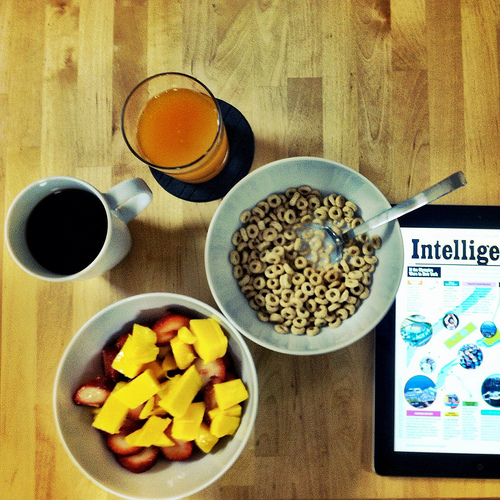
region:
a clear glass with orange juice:
[116, 65, 235, 190]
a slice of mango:
[184, 315, 234, 367]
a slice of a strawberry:
[68, 375, 115, 412]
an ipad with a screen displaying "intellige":
[368, 182, 498, 480]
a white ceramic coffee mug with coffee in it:
[3, 162, 154, 288]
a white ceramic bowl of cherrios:
[202, 150, 410, 355]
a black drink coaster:
[139, 89, 267, 204]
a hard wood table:
[1, 0, 498, 496]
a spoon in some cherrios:
[294, 165, 474, 275]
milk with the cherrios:
[283, 215, 363, 273]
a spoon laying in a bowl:
[221, 171, 461, 255]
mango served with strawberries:
[101, 325, 201, 445]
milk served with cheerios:
[280, 235, 346, 299]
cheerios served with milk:
[283, 232, 358, 339]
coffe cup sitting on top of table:
[1, 185, 157, 295]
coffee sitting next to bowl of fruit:
[16, 176, 153, 317]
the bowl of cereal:
[203, 155, 403, 355]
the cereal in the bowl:
[228, 185, 381, 336]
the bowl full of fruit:
[52, 291, 257, 498]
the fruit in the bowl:
[72, 313, 248, 473]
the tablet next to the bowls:
[371, 204, 498, 479]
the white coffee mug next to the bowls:
[4, 176, 152, 282]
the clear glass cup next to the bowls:
[120, 71, 228, 183]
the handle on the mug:
[104, 177, 151, 224]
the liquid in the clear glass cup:
[137, 88, 229, 184]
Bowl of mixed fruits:
[47, 292, 249, 498]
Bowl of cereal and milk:
[206, 157, 401, 359]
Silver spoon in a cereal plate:
[291, 169, 480, 270]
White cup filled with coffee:
[8, 165, 150, 280]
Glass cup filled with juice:
[118, 71, 231, 184]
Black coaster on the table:
[149, 95, 258, 199]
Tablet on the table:
[368, 200, 498, 478]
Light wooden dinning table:
[0, 0, 499, 70]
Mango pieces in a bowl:
[107, 340, 199, 420]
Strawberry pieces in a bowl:
[107, 430, 175, 470]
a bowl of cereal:
[212, 178, 412, 343]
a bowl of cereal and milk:
[217, 149, 401, 340]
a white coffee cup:
[4, 163, 119, 297]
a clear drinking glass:
[118, 43, 239, 188]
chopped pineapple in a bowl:
[94, 321, 220, 438]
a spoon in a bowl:
[280, 159, 464, 276]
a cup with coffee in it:
[5, 156, 109, 301]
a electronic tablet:
[362, 178, 489, 493]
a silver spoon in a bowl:
[290, 166, 465, 263]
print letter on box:
[411, 236, 421, 258]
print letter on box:
[421, 242, 434, 261]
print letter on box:
[453, 238, 460, 264]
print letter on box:
[459, 238, 467, 260]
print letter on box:
[469, 236, 476, 261]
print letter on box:
[476, 240, 492, 269]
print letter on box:
[490, 243, 498, 264]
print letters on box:
[408, 236, 497, 264]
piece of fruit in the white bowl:
[186, 315, 224, 361]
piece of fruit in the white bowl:
[210, 380, 251, 408]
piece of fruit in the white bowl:
[205, 410, 240, 445]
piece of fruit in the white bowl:
[170, 400, 207, 446]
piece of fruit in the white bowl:
[91, 380, 128, 436]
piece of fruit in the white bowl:
[120, 406, 172, 447]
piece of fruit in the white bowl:
[115, 331, 146, 378]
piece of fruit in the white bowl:
[70, 380, 108, 412]